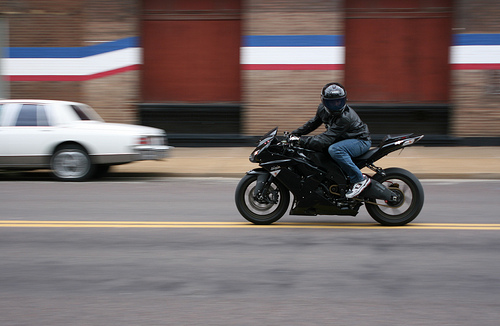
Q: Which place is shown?
A: It is a street.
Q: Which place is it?
A: It is a street.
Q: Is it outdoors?
A: Yes, it is outdoors.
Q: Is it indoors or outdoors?
A: It is outdoors.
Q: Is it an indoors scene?
A: No, it is outdoors.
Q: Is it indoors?
A: No, it is outdoors.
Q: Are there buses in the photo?
A: No, there are no buses.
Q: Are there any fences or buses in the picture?
A: No, there are no buses or fences.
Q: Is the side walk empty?
A: Yes, the side walk is empty.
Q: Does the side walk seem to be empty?
A: Yes, the side walk is empty.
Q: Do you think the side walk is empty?
A: Yes, the side walk is empty.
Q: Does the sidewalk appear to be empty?
A: Yes, the sidewalk is empty.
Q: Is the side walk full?
A: No, the side walk is empty.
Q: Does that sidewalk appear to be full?
A: No, the sidewalk is empty.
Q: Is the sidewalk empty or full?
A: The sidewalk is empty.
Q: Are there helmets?
A: Yes, there is a helmet.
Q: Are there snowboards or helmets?
A: Yes, there is a helmet.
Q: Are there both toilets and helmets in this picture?
A: No, there is a helmet but no toilets.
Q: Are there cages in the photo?
A: No, there are no cages.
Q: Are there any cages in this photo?
A: No, there are no cages.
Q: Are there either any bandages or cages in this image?
A: No, there are no cages or bandages.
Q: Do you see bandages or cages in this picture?
A: No, there are no cages or bandages.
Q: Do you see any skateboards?
A: No, there are no skateboards.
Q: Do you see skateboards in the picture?
A: No, there are no skateboards.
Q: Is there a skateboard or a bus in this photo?
A: No, there are no skateboards or buses.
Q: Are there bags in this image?
A: No, there are no bags.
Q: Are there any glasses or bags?
A: No, there are no bags or glasses.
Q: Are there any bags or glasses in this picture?
A: No, there are no bags or glasses.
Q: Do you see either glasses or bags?
A: No, there are no bags or glasses.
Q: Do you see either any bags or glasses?
A: No, there are no bags or glasses.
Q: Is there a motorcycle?
A: Yes, there is a motorcycle.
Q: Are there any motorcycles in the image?
A: Yes, there is a motorcycle.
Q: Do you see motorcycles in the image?
A: Yes, there is a motorcycle.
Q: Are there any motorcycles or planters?
A: Yes, there is a motorcycle.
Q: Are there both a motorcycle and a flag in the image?
A: No, there is a motorcycle but no flags.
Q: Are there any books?
A: No, there are no books.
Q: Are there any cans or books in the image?
A: No, there are no books or cans.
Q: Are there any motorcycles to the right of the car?
A: Yes, there is a motorcycle to the right of the car.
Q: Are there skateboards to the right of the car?
A: No, there is a motorcycle to the right of the car.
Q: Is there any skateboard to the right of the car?
A: No, there is a motorcycle to the right of the car.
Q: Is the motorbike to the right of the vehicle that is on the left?
A: Yes, the motorbike is to the right of the car.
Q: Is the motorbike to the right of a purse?
A: No, the motorbike is to the right of the car.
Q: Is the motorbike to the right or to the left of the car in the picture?
A: The motorbike is to the right of the car.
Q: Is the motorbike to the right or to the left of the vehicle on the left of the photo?
A: The motorbike is to the right of the car.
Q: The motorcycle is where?
A: The motorcycle is on the street.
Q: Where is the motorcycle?
A: The motorcycle is on the street.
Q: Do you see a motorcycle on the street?
A: Yes, there is a motorcycle on the street.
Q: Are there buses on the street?
A: No, there is a motorcycle on the street.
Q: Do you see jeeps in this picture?
A: No, there are no jeeps.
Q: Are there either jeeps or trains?
A: No, there are no jeeps or trains.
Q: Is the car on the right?
A: No, the car is on the left of the image.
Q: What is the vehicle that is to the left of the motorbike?
A: The vehicle is a car.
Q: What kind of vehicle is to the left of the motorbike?
A: The vehicle is a car.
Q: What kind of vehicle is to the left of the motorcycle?
A: The vehicle is a car.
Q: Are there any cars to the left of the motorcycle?
A: Yes, there is a car to the left of the motorcycle.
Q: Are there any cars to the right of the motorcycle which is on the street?
A: No, the car is to the left of the motorbike.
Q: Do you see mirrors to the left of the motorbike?
A: No, there is a car to the left of the motorbike.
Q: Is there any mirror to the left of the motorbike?
A: No, there is a car to the left of the motorbike.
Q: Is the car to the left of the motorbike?
A: Yes, the car is to the left of the motorbike.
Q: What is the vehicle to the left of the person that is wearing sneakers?
A: The vehicle is a car.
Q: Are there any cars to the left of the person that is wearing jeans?
A: Yes, there is a car to the left of the person.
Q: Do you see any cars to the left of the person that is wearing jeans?
A: Yes, there is a car to the left of the person.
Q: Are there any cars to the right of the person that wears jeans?
A: No, the car is to the left of the person.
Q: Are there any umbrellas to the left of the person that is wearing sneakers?
A: No, there is a car to the left of the person.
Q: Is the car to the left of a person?
A: Yes, the car is to the left of a person.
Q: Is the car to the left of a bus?
A: No, the car is to the left of a person.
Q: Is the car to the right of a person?
A: No, the car is to the left of a person.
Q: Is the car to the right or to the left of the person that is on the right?
A: The car is to the left of the person.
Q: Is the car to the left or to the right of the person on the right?
A: The car is to the left of the person.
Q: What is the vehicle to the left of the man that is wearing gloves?
A: The vehicle is a car.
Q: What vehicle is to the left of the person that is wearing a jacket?
A: The vehicle is a car.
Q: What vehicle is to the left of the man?
A: The vehicle is a car.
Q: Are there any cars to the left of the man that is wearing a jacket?
A: Yes, there is a car to the left of the man.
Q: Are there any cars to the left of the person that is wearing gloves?
A: Yes, there is a car to the left of the man.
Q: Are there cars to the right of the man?
A: No, the car is to the left of the man.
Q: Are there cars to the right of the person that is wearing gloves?
A: No, the car is to the left of the man.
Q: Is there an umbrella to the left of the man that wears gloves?
A: No, there is a car to the left of the man.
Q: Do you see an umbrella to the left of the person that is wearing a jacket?
A: No, there is a car to the left of the man.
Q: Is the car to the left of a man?
A: Yes, the car is to the left of a man.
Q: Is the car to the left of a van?
A: No, the car is to the left of a man.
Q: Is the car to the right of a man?
A: No, the car is to the left of a man.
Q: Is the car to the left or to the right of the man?
A: The car is to the left of the man.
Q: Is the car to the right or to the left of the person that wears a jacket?
A: The car is to the left of the man.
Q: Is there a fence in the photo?
A: No, there are no fences.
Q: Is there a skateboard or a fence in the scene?
A: No, there are no fences or skateboards.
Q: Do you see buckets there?
A: No, there are no buckets.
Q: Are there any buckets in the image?
A: No, there are no buckets.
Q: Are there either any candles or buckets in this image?
A: No, there are no buckets or candles.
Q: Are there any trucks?
A: No, there are no trucks.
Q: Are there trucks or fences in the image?
A: No, there are no trucks or fences.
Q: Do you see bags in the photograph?
A: No, there are no bags.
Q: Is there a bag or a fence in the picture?
A: No, there are no bags or fences.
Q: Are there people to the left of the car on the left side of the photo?
A: No, the person is to the right of the car.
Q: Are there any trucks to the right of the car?
A: No, there is a person to the right of the car.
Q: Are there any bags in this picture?
A: No, there are no bags.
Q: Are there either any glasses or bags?
A: No, there are no bags or glasses.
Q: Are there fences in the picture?
A: No, there are no fences.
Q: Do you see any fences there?
A: No, there are no fences.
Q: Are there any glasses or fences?
A: No, there are no fences or glasses.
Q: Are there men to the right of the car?
A: Yes, there is a man to the right of the car.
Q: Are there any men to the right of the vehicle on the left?
A: Yes, there is a man to the right of the car.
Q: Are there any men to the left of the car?
A: No, the man is to the right of the car.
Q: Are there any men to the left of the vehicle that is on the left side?
A: No, the man is to the right of the car.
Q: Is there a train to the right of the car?
A: No, there is a man to the right of the car.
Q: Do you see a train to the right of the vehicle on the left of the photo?
A: No, there is a man to the right of the car.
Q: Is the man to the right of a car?
A: Yes, the man is to the right of a car.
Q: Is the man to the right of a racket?
A: No, the man is to the right of a car.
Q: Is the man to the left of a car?
A: No, the man is to the right of a car.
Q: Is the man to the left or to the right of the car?
A: The man is to the right of the car.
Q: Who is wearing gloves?
A: The man is wearing gloves.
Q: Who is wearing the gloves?
A: The man is wearing gloves.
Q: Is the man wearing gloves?
A: Yes, the man is wearing gloves.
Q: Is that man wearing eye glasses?
A: No, the man is wearing gloves.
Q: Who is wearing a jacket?
A: The man is wearing a jacket.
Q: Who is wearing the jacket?
A: The man is wearing a jacket.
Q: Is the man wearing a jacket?
A: Yes, the man is wearing a jacket.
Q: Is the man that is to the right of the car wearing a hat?
A: No, the man is wearing a jacket.